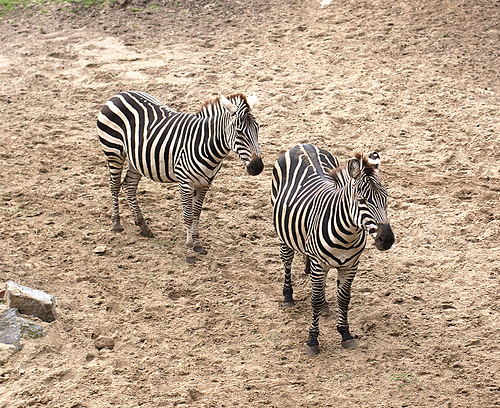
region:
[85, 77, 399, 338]
these are two zebras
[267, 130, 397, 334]
the zebra is standing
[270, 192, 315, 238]
the belly is fat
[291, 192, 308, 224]
the zebra is white and black in color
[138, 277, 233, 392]
the ground is full of sand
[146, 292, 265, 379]
the sand is brown in color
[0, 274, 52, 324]
the rock are small in size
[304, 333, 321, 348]
the leg is black in color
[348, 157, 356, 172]
this is the ear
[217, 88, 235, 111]
the ear is long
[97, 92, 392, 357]
two zebras standing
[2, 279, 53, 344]
rocks on ground in zebra habitat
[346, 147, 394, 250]
head of the zebra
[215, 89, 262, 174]
head of the zebra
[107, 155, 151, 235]
zebra's hind legs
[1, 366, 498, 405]
sand on the ground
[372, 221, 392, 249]
nose of the zebra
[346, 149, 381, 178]
ears on the zebra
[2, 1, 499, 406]
zebra habitat with two zebras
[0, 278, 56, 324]
medium rock on the ground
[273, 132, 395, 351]
A zebra standing in dirt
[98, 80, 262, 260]
A zebra standing in dirt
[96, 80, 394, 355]
A pair of zebras standing in the dirt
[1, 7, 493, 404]
A dirt field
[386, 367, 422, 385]
some grass in the dirt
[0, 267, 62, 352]
some large rocks in the dirt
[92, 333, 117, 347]
A rock in the dirt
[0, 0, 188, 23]
A small patch of grass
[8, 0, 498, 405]
hoof prints in the dirt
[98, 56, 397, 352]
two zebras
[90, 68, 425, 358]
two zebras standing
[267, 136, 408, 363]
first zebra among the two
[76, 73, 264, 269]
zebra standing behind other zebra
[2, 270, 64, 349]
rocks sitting in the dirt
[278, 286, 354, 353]
black feet of first zebra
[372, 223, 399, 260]
black nose of first zebra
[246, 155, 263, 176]
black nose of second zebra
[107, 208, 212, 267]
feet of second zebra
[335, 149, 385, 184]
ears of first zebra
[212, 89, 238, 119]
ear of second zebra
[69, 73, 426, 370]
two zebras just standing around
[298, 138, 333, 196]
thick black stripe down middle of back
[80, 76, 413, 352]
two black and white zebras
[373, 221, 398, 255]
a black nose of zebra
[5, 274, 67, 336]
a big white stone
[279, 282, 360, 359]
black area of leg above hooves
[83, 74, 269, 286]
One zebra behind the other zebra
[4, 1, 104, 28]
a little bit of grass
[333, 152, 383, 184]
One ear standing straight up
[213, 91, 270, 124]
two white ears on zebra